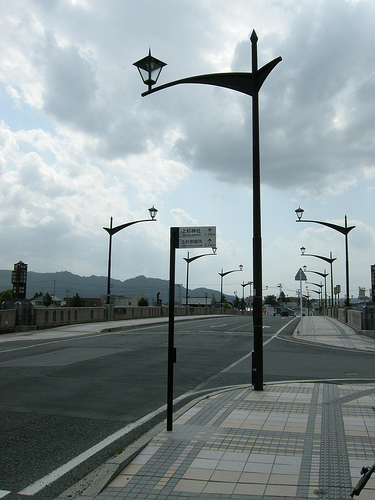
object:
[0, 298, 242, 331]
bridge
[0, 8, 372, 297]
skies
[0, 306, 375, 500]
street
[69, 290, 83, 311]
trees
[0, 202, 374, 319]
background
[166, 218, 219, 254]
sign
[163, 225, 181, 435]
pole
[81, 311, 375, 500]
two roads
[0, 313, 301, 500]
pavement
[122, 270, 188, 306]
mountains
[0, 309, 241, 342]
area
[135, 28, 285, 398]
street lamp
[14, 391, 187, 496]
line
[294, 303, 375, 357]
crosswalk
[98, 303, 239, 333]
pushed up section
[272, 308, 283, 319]
cars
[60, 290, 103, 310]
buildings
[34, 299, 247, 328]
fence